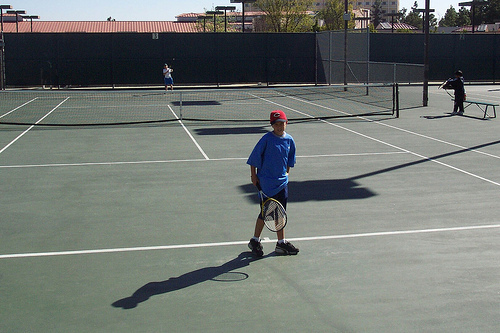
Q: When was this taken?
A: Daytime.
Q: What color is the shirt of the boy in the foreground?
A: Blue.